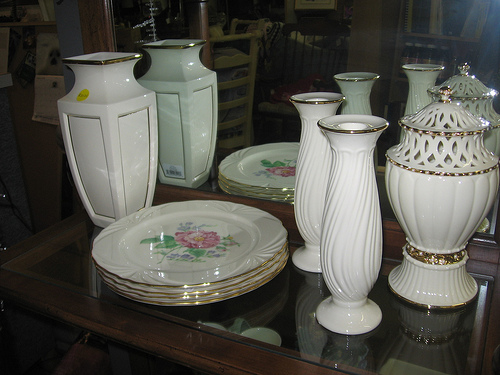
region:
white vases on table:
[75, 34, 212, 246]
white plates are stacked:
[95, 168, 287, 316]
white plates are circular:
[110, 121, 311, 321]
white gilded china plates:
[94, 171, 269, 316]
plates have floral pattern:
[75, 176, 263, 304]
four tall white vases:
[280, 56, 429, 355]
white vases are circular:
[273, 42, 453, 318]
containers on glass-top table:
[35, 36, 486, 317]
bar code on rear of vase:
[153, 147, 186, 202]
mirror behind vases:
[77, 4, 319, 246]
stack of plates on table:
[82, 185, 292, 322]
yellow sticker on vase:
[70, 83, 95, 106]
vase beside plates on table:
[51, 41, 163, 243]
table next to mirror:
[3, 171, 498, 373]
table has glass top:
[10, 188, 490, 373]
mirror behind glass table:
[73, 1, 499, 274]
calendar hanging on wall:
[22, 30, 74, 132]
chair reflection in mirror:
[179, 21, 282, 166]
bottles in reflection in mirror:
[391, 33, 458, 87]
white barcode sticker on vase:
[157, 158, 189, 185]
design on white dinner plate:
[146, 220, 243, 274]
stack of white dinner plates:
[77, 195, 288, 310]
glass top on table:
[250, 293, 312, 343]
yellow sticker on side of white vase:
[64, 82, 101, 111]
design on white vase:
[412, 135, 474, 173]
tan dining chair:
[210, 34, 274, 151]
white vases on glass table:
[297, 67, 397, 342]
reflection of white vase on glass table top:
[380, 300, 479, 374]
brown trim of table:
[122, 310, 177, 350]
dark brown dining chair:
[268, 22, 340, 90]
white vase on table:
[294, 98, 439, 332]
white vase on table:
[244, 65, 386, 353]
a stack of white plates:
[96, 200, 293, 312]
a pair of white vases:
[288, 82, 400, 336]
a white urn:
[383, 76, 498, 316]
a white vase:
[57, 41, 155, 234]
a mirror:
[107, 1, 499, 245]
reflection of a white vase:
[149, 29, 216, 189]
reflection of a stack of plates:
[191, 137, 316, 210]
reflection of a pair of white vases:
[336, 52, 439, 118]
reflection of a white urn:
[418, 57, 498, 124]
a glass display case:
[37, 176, 491, 372]